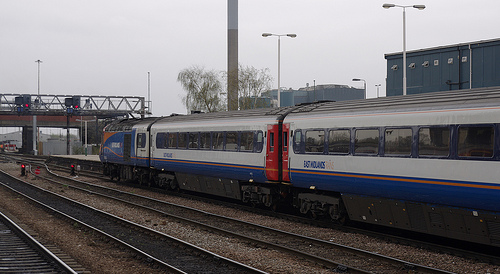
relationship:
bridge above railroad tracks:
[1, 91, 151, 132] [48, 157, 439, 271]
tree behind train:
[175, 61, 277, 110] [86, 77, 499, 242]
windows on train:
[301, 127, 498, 164] [93, 96, 498, 243]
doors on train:
[265, 122, 292, 181] [98, 119, 498, 183]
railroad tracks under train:
[142, 189, 439, 264] [97, 86, 499, 256]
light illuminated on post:
[68, 162, 75, 167] [68, 160, 77, 175]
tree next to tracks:
[176, 66, 225, 112] [28, 152, 442, 270]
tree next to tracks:
[222, 64, 272, 108] [28, 152, 442, 270]